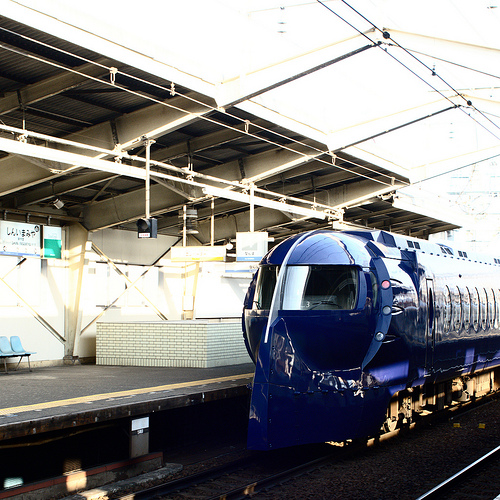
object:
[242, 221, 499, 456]
train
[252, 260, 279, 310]
window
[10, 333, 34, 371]
chair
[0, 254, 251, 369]
wall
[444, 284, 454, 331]
window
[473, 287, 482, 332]
window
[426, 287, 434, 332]
window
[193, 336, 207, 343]
brick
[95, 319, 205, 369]
wall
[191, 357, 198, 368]
brick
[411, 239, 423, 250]
window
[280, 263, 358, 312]
window